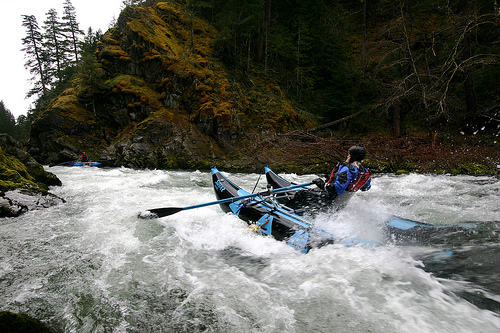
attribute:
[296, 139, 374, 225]
person — rafting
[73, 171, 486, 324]
river — white, moving, clean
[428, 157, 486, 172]
vegetation — green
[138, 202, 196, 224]
paddle — long, light blue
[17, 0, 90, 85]
tree — green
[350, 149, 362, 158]
helmet — black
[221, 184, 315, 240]
raft — blue, black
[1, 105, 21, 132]
tree — green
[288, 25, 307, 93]
tree — green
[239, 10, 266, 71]
tree — gren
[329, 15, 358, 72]
tree — green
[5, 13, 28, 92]
sky — clear